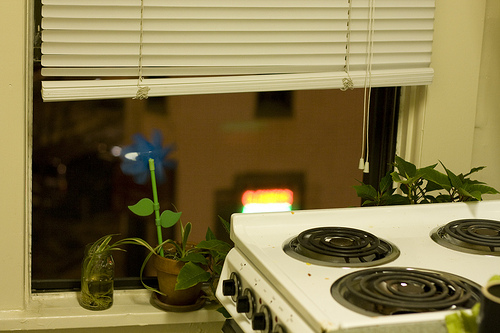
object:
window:
[1, 1, 424, 321]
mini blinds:
[41, 38, 434, 56]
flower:
[113, 125, 179, 263]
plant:
[347, 150, 500, 209]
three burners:
[266, 208, 499, 324]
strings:
[354, 1, 377, 175]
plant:
[67, 230, 161, 314]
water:
[72, 274, 120, 313]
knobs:
[231, 285, 256, 322]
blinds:
[34, 0, 449, 103]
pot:
[149, 243, 210, 315]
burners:
[277, 221, 409, 268]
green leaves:
[411, 166, 450, 186]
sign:
[236, 183, 297, 214]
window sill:
[2, 279, 235, 332]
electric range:
[208, 193, 500, 333]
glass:
[73, 243, 117, 312]